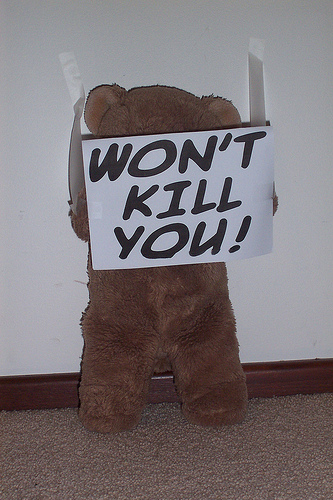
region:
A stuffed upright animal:
[70, 65, 278, 435]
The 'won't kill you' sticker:
[79, 130, 275, 270]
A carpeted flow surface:
[0, 391, 331, 498]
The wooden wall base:
[0, 358, 331, 412]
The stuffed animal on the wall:
[50, 37, 273, 434]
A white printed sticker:
[56, 51, 278, 270]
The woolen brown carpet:
[0, 393, 331, 499]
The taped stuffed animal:
[70, 81, 246, 431]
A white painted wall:
[0, 0, 332, 377]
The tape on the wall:
[55, 48, 276, 136]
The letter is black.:
[84, 141, 134, 186]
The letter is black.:
[127, 138, 179, 177]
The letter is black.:
[177, 133, 219, 176]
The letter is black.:
[232, 126, 266, 172]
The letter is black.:
[216, 171, 243, 216]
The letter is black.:
[190, 173, 217, 216]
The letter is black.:
[155, 178, 190, 222]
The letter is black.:
[119, 180, 163, 222]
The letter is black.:
[109, 221, 145, 266]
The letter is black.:
[187, 213, 230, 261]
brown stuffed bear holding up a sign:
[64, 78, 279, 434]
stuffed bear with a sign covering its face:
[48, 35, 281, 434]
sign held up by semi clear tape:
[45, 32, 281, 270]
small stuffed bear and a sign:
[58, 81, 280, 436]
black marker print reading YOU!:
[111, 215, 254, 262]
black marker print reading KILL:
[118, 176, 250, 222]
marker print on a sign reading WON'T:
[87, 131, 266, 185]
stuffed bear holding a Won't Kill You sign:
[71, 78, 283, 436]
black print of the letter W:
[84, 140, 132, 184]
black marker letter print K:
[117, 182, 160, 222]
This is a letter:
[87, 138, 132, 186]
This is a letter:
[127, 136, 181, 175]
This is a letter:
[175, 134, 217, 173]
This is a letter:
[231, 129, 273, 173]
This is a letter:
[119, 180, 160, 222]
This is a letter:
[158, 176, 193, 219]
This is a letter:
[192, 175, 215, 222]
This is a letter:
[211, 172, 246, 218]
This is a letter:
[106, 223, 148, 265]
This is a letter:
[138, 219, 200, 267]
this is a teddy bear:
[42, 52, 275, 419]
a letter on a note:
[105, 219, 142, 260]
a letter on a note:
[143, 222, 196, 271]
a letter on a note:
[184, 214, 225, 266]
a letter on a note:
[113, 175, 155, 219]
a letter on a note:
[153, 175, 200, 219]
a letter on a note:
[185, 178, 218, 215]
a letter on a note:
[206, 169, 245, 222]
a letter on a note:
[85, 134, 130, 182]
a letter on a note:
[127, 139, 176, 178]